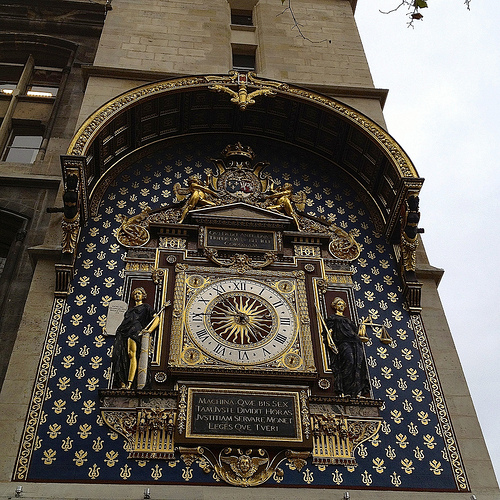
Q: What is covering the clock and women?
A: Arch.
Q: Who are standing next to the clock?
A: Two women.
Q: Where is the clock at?
A: Corner of the building.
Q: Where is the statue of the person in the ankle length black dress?
A: On the right side of the clock.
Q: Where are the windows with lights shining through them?
A: To the left of the clock.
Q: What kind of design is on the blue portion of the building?
A: A gold pattern.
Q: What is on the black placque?
A: Gold lettering.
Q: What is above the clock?
A: A sculpure of a rooftop on a placque.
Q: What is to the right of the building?
A: Light blue sky and white clouds.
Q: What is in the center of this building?
A: A clock.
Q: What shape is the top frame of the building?
A: An arch.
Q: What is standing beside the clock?
A: Human figures.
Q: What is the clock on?
A: The front wall.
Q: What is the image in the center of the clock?
A: A sun.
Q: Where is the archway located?
A: Above the clock.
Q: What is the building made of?
A: Brick.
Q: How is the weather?
A: Partly cloudy.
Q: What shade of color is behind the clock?
A: Dark Blue.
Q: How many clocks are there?
A: One.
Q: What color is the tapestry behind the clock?
A: Blue.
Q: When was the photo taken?
A: Daytime.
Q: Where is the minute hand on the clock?
A: Forty five.